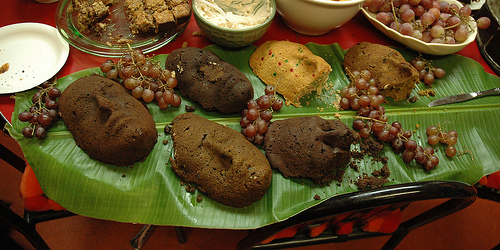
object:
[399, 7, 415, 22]
grapes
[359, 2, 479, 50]
bowl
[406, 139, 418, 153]
grapes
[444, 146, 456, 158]
grapes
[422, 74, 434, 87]
grapes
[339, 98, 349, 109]
grapes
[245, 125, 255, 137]
grapes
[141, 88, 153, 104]
grapes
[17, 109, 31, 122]
grapes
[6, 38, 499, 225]
leaf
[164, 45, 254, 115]
cookies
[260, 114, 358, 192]
cookies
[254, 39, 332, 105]
cookies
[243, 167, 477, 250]
chair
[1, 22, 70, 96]
plate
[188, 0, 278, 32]
bowl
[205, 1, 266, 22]
frosting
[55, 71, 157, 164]
cookies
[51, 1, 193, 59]
dish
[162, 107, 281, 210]
cookies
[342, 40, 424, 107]
cookies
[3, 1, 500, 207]
table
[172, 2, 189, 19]
brownies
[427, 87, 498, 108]
knife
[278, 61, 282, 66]
dots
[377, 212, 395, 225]
cushion